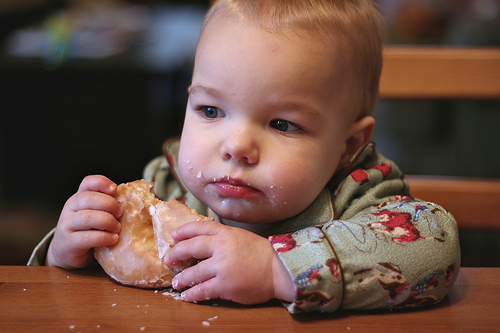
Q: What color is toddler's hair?
A: Blonde.